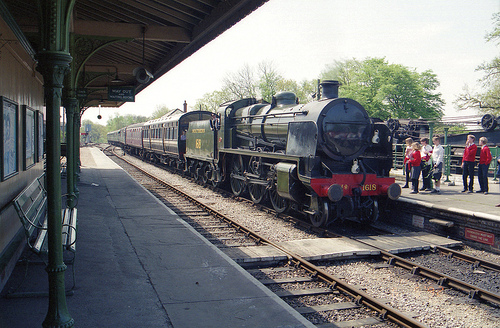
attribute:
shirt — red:
[461, 145, 479, 164]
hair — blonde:
[412, 142, 421, 150]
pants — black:
[461, 160, 476, 192]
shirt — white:
[431, 145, 447, 165]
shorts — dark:
[434, 162, 444, 181]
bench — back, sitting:
[14, 176, 79, 297]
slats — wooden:
[246, 265, 358, 315]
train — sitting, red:
[107, 80, 403, 229]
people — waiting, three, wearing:
[402, 135, 493, 195]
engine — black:
[228, 81, 403, 232]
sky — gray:
[80, 1, 498, 127]